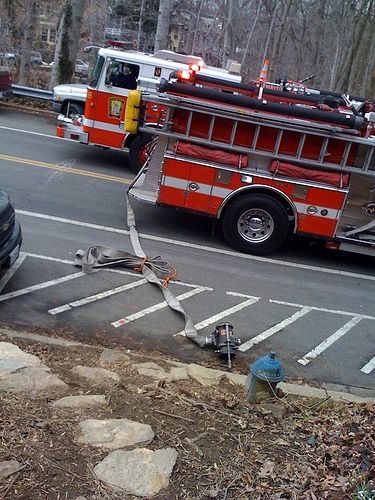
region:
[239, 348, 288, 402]
a blue fire hydrant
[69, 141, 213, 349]
a gray fire hose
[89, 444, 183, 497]
a gray rock in the dirt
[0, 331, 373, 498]
brown dirt on the ground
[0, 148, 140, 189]
a yellow line on the road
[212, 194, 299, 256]
a black tire on the fire engine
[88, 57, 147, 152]
the door of the fire engine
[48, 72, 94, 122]
the front of a truck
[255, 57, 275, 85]
an orange and white cone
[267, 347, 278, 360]
a bolt on the hydrant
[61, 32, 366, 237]
two fire trucks on the road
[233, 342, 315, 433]
a blue fire hydrant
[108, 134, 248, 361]
a fire truck hose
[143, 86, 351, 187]
a fire truck ladder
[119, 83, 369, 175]
a ladder on the side of a truck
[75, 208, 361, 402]
white street lines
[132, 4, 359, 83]
trees in the background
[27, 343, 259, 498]
a dirt and rocky area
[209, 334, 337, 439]
a fire hydrant on the side of the road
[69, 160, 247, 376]
a fire hose laying on the road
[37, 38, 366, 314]
two red fire trucks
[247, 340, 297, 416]
a blue fire hydrant on the ground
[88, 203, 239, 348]
a fire truck hose on the ground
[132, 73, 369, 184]
a fire truck ladder on the side of a truck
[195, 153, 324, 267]
a fire truck wheel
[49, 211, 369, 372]
white lines painted on the road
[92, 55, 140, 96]
a man in the fire truck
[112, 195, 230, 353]
a thick fire hose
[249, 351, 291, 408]
the fire hydrant is blue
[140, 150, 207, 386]
a fire hose in the road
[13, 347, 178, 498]
rocks in the dirt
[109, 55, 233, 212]
fire truck is red and white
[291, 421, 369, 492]
leaves on the ground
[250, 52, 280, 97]
orange cone on top of fire truck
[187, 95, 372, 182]
ladder on the side of a fire truck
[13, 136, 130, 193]
yellow lines in the road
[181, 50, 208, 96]
fire lights are on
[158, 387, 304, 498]
twigs in the dirt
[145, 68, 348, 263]
Back end of fire truck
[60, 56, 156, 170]
Front of a fire truck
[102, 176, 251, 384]
Fire hose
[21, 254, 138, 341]
Painted lines on the side of the road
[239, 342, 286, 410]
Blue fire hydrant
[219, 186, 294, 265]
Back tire of a fire truck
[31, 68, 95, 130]
Truck parked on the side of the road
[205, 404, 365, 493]
Old dry leaves on the ground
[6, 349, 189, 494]
Stones on the ground by the road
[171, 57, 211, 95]
Red lights on top of fire truck